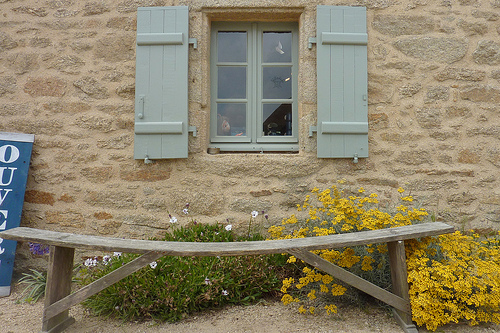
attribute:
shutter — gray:
[126, 4, 193, 165]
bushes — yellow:
[262, 172, 498, 328]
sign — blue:
[1, 124, 44, 300]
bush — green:
[70, 203, 297, 332]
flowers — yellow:
[407, 231, 498, 331]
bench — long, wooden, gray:
[2, 220, 455, 331]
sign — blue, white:
[0, 133, 36, 296]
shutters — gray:
[314, 5, 371, 158]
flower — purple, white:
[78, 249, 283, 323]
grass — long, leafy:
[14, 268, 44, 302]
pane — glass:
[218, 30, 246, 60]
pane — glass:
[263, 32, 292, 62]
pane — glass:
[217, 65, 245, 97]